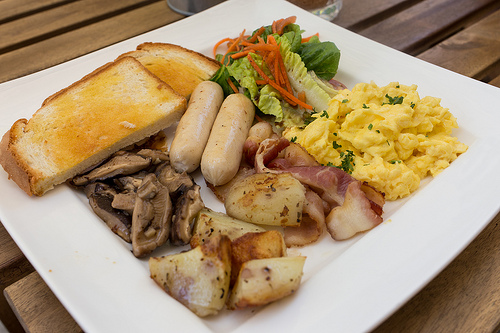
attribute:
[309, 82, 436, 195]
egg — with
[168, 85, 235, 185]
links — sausage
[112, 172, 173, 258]
mushroom — on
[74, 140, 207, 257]
muchrooms — brown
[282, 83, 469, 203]
food — yellow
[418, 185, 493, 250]
plate — white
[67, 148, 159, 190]
mushroom — brown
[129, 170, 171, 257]
mushroom — brown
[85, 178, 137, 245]
mushroom — brown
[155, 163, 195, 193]
mushroom — brown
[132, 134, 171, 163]
mushroom — brown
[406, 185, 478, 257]
plate — white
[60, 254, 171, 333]
edge — on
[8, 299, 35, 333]
edge — on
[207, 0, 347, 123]
vegetables — large